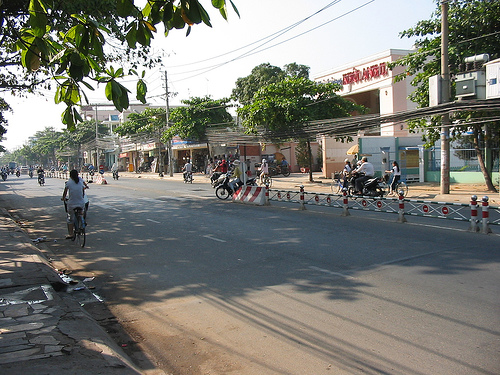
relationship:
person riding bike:
[64, 168, 87, 236] [63, 194, 88, 245]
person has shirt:
[230, 157, 243, 197] [230, 167, 242, 178]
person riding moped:
[230, 157, 243, 197] [217, 177, 251, 198]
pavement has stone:
[3, 206, 116, 374] [4, 331, 59, 362]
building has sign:
[252, 49, 436, 174] [343, 62, 388, 88]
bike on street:
[63, 194, 88, 245] [4, 161, 496, 374]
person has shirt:
[64, 168, 87, 236] [68, 178, 85, 204]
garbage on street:
[53, 263, 97, 290] [4, 161, 496, 374]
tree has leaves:
[231, 64, 309, 98] [255, 75, 272, 84]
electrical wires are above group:
[193, 108, 498, 147] [339, 153, 407, 196]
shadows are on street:
[26, 185, 485, 298] [4, 161, 496, 374]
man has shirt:
[181, 156, 193, 181] [184, 161, 193, 174]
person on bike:
[64, 168, 87, 236] [63, 194, 88, 245]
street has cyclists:
[4, 161, 496, 374] [3, 161, 48, 191]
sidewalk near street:
[3, 206, 116, 374] [4, 161, 496, 374]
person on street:
[64, 168, 87, 236] [4, 161, 496, 374]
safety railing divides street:
[265, 185, 496, 233] [4, 161, 496, 374]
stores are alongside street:
[49, 60, 421, 176] [4, 161, 496, 374]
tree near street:
[245, 76, 368, 179] [4, 161, 496, 374]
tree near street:
[391, 1, 500, 194] [4, 161, 496, 374]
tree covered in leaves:
[231, 64, 309, 98] [255, 75, 272, 84]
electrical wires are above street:
[193, 108, 498, 147] [4, 161, 496, 374]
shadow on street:
[193, 282, 497, 374] [4, 161, 496, 374]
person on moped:
[230, 157, 243, 197] [217, 177, 251, 198]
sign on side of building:
[343, 62, 388, 88] [252, 49, 436, 174]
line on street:
[143, 215, 162, 225] [4, 161, 496, 374]